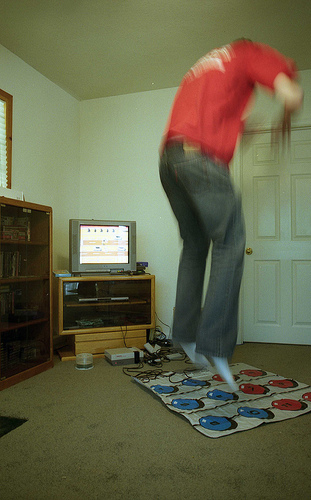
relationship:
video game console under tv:
[105, 345, 144, 364] [69, 218, 136, 273]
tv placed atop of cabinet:
[69, 218, 136, 273] [56, 270, 155, 360]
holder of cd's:
[76, 352, 94, 370] [77, 358, 92, 366]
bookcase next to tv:
[0, 193, 55, 392] [69, 218, 136, 273]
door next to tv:
[235, 119, 310, 348] [69, 218, 136, 273]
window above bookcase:
[0, 87, 14, 188] [0, 193, 55, 392]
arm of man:
[250, 40, 303, 110] [153, 36, 304, 395]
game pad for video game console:
[130, 360, 310, 442] [105, 345, 144, 364]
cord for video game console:
[120, 356, 149, 384] [105, 345, 144, 364]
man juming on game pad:
[153, 36, 304, 395] [130, 360, 310, 442]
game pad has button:
[130, 360, 310, 442] [272, 395, 304, 413]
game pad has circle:
[130, 360, 310, 442] [199, 414, 233, 432]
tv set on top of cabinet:
[69, 218, 136, 273] [56, 270, 155, 360]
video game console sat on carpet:
[105, 345, 144, 364] [0, 336, 310, 499]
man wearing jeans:
[153, 36, 304, 395] [159, 143, 247, 358]